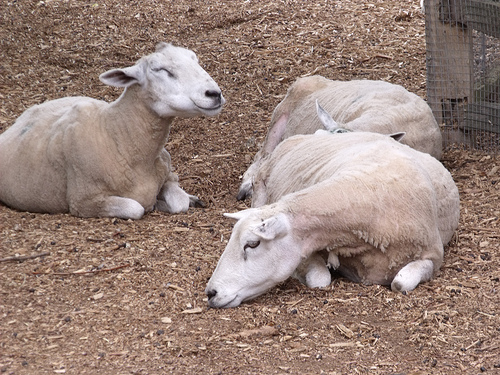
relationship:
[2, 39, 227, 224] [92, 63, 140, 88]
lamb has ear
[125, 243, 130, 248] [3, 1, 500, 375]
wood chip on ground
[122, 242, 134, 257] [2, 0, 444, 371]
wood chip on ground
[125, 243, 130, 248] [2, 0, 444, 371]
wood chip on ground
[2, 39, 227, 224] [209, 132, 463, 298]
lamb next to lamb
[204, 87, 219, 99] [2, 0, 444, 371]
nose on ground